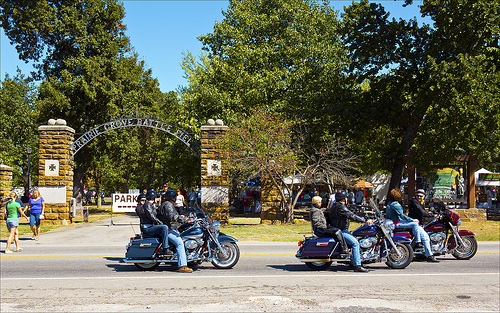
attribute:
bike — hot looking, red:
[296, 203, 412, 271]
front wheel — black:
[388, 240, 414, 267]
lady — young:
[311, 194, 342, 247]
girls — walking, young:
[5, 191, 45, 253]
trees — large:
[0, 3, 490, 190]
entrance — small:
[37, 117, 228, 229]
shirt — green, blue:
[7, 202, 22, 221]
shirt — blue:
[29, 197, 43, 212]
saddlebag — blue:
[308, 228, 336, 243]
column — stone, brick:
[35, 123, 72, 220]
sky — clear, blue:
[2, 3, 427, 90]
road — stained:
[0, 246, 498, 310]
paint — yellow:
[2, 248, 499, 260]